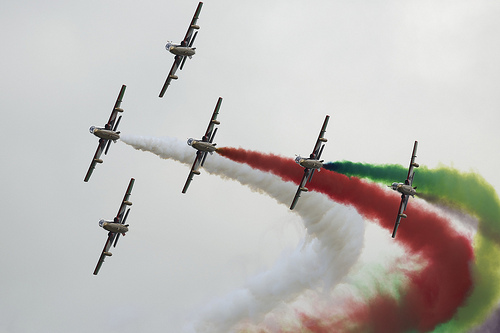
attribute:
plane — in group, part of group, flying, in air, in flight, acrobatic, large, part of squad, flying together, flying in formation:
[84, 84, 126, 184]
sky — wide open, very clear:
[1, 1, 499, 333]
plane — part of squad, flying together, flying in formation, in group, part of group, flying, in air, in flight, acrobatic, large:
[158, 2, 203, 99]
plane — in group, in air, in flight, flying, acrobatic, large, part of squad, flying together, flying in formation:
[93, 176, 135, 276]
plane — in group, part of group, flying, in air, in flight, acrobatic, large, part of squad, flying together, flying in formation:
[180, 95, 224, 195]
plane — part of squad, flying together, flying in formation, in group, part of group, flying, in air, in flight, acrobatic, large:
[289, 115, 331, 212]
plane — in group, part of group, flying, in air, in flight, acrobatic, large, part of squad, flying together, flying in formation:
[390, 141, 419, 239]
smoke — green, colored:
[322, 162, 499, 332]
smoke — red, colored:
[217, 147, 477, 332]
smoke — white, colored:
[120, 135, 366, 332]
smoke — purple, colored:
[416, 192, 499, 332]